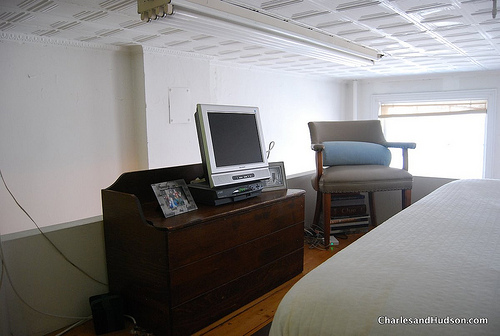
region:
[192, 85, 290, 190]
a tv monitor on stand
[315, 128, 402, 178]
a blue pillow on chair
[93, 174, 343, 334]
a brown wooden piece of funiture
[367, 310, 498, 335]
photographer's name in the corner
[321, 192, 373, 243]
a stack of books under chair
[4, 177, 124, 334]
black wire coming down from wall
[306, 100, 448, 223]
a gray chair by window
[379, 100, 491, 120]
white rolled up blinds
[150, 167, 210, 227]
a picture by the tv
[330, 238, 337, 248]
a little green light on floor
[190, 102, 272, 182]
Silver TV on wooden dresser.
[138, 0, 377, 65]
Light fixture on white ceiling.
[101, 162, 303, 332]
Dark brown dresser in a room.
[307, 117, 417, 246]
Light brown chair in a room.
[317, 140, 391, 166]
Blue pillow on light brown chair.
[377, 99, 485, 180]
Window with blinds open.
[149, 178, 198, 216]
Picture on the dresser to the left of TV.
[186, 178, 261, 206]
VCR is sitting under the TV.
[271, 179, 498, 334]
A bed in a very plain room.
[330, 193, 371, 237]
A stack of books under a tan chair.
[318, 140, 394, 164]
The blue pillow on the chair.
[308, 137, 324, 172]
The left armrest of the chair.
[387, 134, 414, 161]
The right armrest of the chair.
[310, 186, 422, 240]
The legs of the chair.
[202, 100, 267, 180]
The t.v. on the brown dresser.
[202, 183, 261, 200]
The cable box below the t.v.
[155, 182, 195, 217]
The picture frame on the left.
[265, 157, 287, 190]
The picture frame on the right.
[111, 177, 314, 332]
The brown dresser the t.v. is on.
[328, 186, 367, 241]
The stack of books under the chair.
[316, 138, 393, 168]
blue pillow on the chair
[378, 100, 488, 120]
blinds raised on window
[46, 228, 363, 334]
light colored hard wood floor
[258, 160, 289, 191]
picture frame on dresser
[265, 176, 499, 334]
large bed with white comforter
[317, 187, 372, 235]
stack of books under chair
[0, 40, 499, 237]
white upper half of wall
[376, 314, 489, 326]
white writing on corner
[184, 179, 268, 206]
black boxes under tv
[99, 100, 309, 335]
display on top of dresser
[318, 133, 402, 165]
Pillow sitting on tan chair.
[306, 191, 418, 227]
Chair has wood legs.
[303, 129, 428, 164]
Chair has wood arm rests.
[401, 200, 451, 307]
White bedspread on bed in room.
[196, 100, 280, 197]
Silver television on dresser in room.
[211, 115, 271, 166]
Television screen is turned off.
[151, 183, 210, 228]
Picture in silver frame.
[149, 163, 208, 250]
Silver frame on dresser.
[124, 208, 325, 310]
Wood dresser in room.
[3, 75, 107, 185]
Top section of wall painted white.